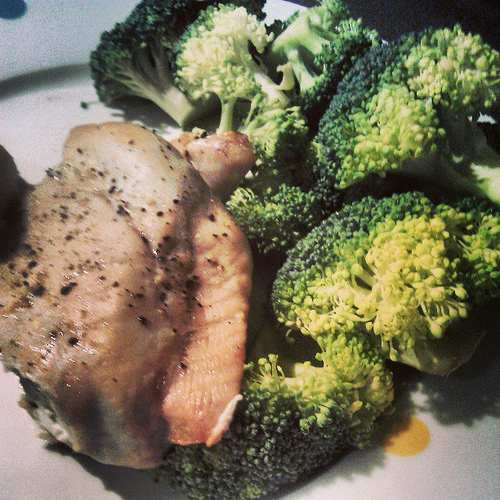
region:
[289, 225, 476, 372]
Broccoli on the plate.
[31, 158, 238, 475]
Meat on the plate.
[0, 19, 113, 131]
The plate is white.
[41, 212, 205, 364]
Seasoning on the meat.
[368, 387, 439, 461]
Grease on the plate.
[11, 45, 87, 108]
Dip in the plate.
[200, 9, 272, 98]
White part of the broccoli.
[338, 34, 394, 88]
Dark green part of the broccoli.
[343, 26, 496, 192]
Large stalk of broccoli.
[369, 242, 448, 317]
Light green on the broccoli.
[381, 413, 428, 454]
small orange dot on plate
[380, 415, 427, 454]
circular orange dot on the plate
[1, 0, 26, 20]
small, blue dot on the plate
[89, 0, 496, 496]
bunch of broccoli on plate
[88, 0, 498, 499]
green broccoli on plate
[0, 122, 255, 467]
piece of meat on the plate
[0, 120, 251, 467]
meat next to broccoli on plate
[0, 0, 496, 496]
plate with healthy meal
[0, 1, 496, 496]
white plate with meat and broccoli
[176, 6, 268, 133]
white piece of broccoli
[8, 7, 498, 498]
a meal of broccoli with meat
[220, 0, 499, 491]
pieces of broccoli on side of dish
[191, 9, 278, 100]
florets of broccoli are white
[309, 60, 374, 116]
florets of broccoli are dark green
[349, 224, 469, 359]
florets of broccoli are light green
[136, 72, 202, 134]
stem of broccoli is green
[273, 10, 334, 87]
two stem of broccoli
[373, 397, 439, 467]
a yellow spot under broccoli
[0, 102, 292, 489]
cooked seasoned beef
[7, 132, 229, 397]
spices over cooked seasoned beef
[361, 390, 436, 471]
Yellow dot on plate.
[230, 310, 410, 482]
Broccoli on white plate.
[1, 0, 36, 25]
Blue dot on plate.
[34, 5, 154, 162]
Plate is white.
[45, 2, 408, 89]
Plate is circular.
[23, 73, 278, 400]
Cut pork on plate.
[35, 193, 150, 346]
Seasoning on crust of meat.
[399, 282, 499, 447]
Shadow from broccoli.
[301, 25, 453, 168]
Dark and light green colors on broccoli.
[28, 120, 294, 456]
Meat is light brown in color.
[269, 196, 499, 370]
The broccoli is green.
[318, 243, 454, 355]
Yellow spot on the broccoli.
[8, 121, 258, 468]
The chicken is on top of the broccoli.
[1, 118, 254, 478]
The chicken is seasoned.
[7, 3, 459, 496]
The food is on the plate.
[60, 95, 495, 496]
The plate is white.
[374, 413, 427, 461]
yellow dot on the plate.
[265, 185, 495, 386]
The broccoli is raw.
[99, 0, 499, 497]
The broccoli is next to the chicken.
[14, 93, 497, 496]
The food is ready to eat.